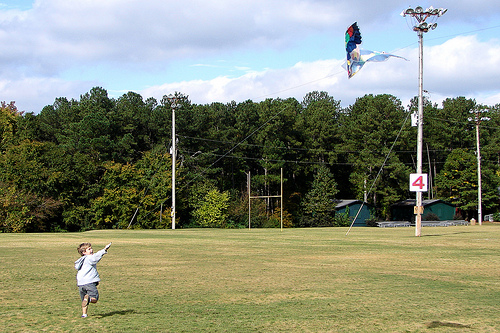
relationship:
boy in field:
[73, 241, 113, 318] [0, 223, 499, 332]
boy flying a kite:
[73, 241, 113, 318] [341, 22, 413, 83]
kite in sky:
[341, 22, 413, 83] [1, 0, 499, 103]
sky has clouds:
[1, 0, 499, 103] [240, 35, 498, 94]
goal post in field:
[247, 167, 285, 231] [0, 223, 499, 332]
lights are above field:
[404, 3, 448, 36] [0, 223, 499, 332]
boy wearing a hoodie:
[73, 241, 113, 318] [74, 252, 106, 283]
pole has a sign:
[406, 32, 429, 240] [409, 172, 429, 192]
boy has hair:
[73, 241, 113, 318] [78, 241, 91, 257]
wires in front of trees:
[177, 134, 478, 164] [0, 87, 498, 232]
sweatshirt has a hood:
[74, 252, 106, 283] [74, 256, 85, 273]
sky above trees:
[1, 0, 499, 103] [0, 87, 498, 232]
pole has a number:
[406, 32, 429, 240] [415, 177, 426, 188]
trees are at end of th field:
[0, 87, 498, 232] [0, 223, 499, 332]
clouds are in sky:
[240, 35, 498, 94] [1, 0, 499, 103]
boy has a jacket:
[73, 241, 113, 318] [74, 252, 106, 283]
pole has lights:
[406, 32, 429, 240] [404, 3, 448, 36]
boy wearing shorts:
[73, 241, 113, 318] [78, 284, 100, 302]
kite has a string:
[341, 22, 413, 83] [108, 72, 348, 249]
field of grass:
[0, 223, 499, 332] [144, 226, 325, 331]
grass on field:
[0, 223, 499, 332] [27, 223, 430, 327]